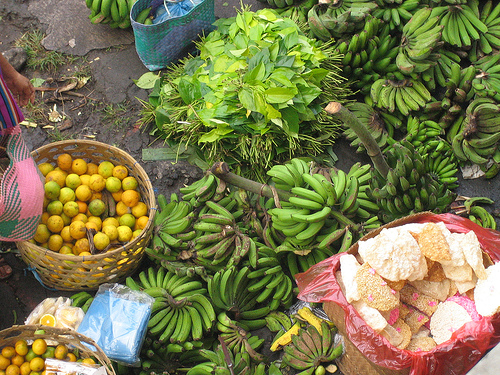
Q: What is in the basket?
A: Bread is in the basket.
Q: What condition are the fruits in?
A: The fruits are fresh.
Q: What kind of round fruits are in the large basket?
A: The round fruits citrus fruits.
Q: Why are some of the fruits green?
A: Some fruits are not yet ripe.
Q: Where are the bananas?
A: The bananas are on the ground.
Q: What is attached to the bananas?
A: A banana tree branch is attached to the bananas.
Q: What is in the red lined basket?
A: Bread.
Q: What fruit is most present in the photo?
A: Plantains.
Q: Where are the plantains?
A: Ground.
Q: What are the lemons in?
A: Basket.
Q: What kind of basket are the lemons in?
A: Weaved.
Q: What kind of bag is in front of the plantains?
A: Blue bag.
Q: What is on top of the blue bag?
A: Handle.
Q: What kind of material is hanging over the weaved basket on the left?
A: Pink and green fabric.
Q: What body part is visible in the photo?
A: Hand.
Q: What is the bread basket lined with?
A: Red plastic.